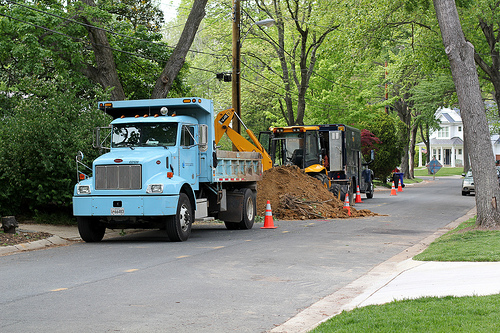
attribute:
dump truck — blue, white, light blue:
[67, 94, 264, 242]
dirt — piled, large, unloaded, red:
[254, 164, 388, 221]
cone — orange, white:
[260, 196, 277, 232]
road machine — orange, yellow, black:
[215, 106, 376, 200]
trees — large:
[0, 0, 213, 226]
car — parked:
[460, 169, 479, 196]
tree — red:
[359, 126, 383, 156]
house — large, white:
[415, 105, 500, 170]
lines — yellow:
[174, 250, 188, 262]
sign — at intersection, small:
[424, 153, 445, 177]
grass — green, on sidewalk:
[301, 292, 499, 332]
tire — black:
[167, 193, 194, 242]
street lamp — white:
[239, 18, 275, 55]